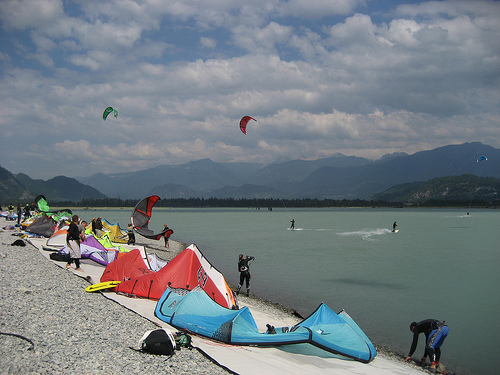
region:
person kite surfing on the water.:
[232, 106, 305, 236]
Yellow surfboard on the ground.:
[80, 273, 123, 300]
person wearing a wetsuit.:
[228, 249, 260, 301]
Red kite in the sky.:
[232, 109, 257, 143]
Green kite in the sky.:
[95, 102, 126, 121]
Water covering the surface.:
[57, 202, 498, 372]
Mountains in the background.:
[1, 140, 498, 207]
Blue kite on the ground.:
[146, 270, 391, 365]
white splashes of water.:
[340, 222, 392, 248]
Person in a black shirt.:
[60, 211, 84, 267]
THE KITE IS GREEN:
[87, 95, 142, 128]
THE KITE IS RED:
[235, 101, 260, 161]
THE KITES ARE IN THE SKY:
[87, 96, 314, 157]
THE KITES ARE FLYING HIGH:
[77, 92, 272, 149]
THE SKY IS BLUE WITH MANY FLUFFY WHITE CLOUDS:
[0, 2, 498, 198]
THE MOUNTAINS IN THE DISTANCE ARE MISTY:
[70, 150, 470, 210]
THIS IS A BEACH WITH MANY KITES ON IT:
[2, 210, 402, 371]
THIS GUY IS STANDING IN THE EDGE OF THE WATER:
[398, 305, 450, 370]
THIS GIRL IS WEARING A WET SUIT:
[227, 245, 265, 302]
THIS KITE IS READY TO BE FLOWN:
[129, 185, 182, 257]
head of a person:
[68, 210, 89, 230]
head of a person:
[234, 250, 251, 260]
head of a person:
[400, 311, 425, 336]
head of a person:
[125, 218, 135, 226]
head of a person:
[88, 212, 104, 222]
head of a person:
[15, 201, 27, 208]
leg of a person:
[51, 247, 85, 273]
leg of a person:
[230, 278, 247, 293]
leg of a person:
[246, 278, 258, 296]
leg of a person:
[428, 342, 443, 373]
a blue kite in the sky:
[95, 100, 135, 125]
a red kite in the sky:
[230, 110, 260, 135]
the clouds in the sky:
[181, 52, 476, 92]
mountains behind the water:
[91, 161, 491, 181]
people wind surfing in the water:
[281, 215, 416, 235]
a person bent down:
[401, 305, 457, 370]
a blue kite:
[160, 295, 361, 350]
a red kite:
[105, 250, 225, 280]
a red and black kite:
[126, 191, 168, 247]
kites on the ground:
[17, 190, 398, 370]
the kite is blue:
[192, 306, 211, 323]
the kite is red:
[123, 267, 138, 283]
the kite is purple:
[88, 238, 100, 249]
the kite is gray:
[136, 215, 145, 225]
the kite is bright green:
[40, 202, 47, 209]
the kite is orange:
[110, 226, 123, 238]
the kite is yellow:
[101, 235, 111, 246]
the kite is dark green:
[106, 110, 112, 117]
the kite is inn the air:
[230, 109, 264, 144]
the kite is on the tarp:
[216, 328, 252, 360]